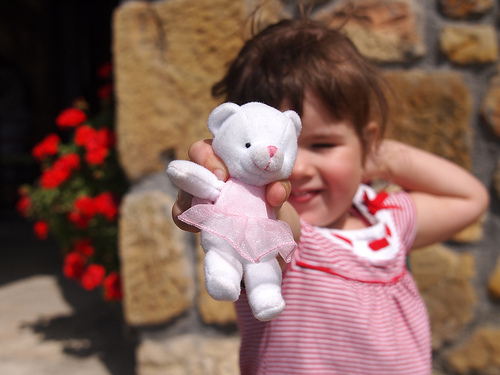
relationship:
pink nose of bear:
[267, 145, 277, 158] [167, 100, 302, 321]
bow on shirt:
[355, 184, 403, 216] [234, 190, 431, 373]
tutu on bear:
[175, 172, 298, 263] [167, 100, 302, 321]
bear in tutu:
[155, 91, 322, 329] [175, 172, 298, 263]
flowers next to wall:
[15, 107, 125, 301] [106, 8, 484, 373]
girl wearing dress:
[168, 9, 493, 371] [259, 185, 459, 367]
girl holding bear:
[168, 9, 493, 371] [167, 102, 305, 321]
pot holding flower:
[51, 251, 155, 373] [43, 100, 122, 152]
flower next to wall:
[43, 100, 122, 152] [76, 47, 202, 349]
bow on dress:
[355, 184, 403, 216] [257, 179, 460, 356]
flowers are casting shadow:
[15, 59, 125, 302] [18, 308, 135, 373]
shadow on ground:
[18, 308, 135, 373] [0, 239, 135, 373]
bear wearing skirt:
[167, 102, 305, 321] [175, 207, 296, 264]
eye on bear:
[244, 140, 251, 150] [167, 100, 302, 321]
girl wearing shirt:
[168, 9, 493, 371] [234, 190, 431, 373]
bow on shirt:
[355, 184, 403, 216] [284, 180, 425, 313]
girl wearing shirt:
[202, 8, 464, 364] [284, 180, 425, 313]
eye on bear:
[244, 140, 251, 150] [171, 79, 311, 316]